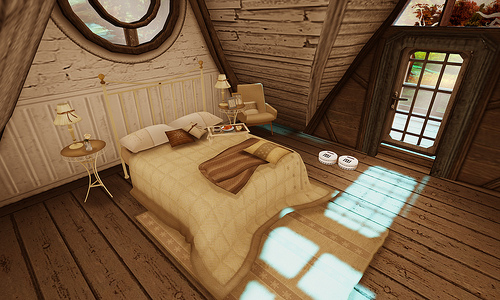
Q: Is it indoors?
A: Yes, it is indoors.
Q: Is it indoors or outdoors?
A: It is indoors.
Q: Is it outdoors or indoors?
A: It is indoors.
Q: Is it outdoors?
A: No, it is indoors.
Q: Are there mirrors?
A: No, there are no mirrors.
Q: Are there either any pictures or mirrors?
A: No, there are no mirrors or pictures.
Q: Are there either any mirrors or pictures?
A: No, there are no mirrors or pictures.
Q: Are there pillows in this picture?
A: Yes, there is a pillow.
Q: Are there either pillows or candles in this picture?
A: Yes, there is a pillow.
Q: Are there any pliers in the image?
A: No, there are no pliers.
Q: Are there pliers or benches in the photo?
A: No, there are no pliers or benches.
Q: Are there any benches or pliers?
A: No, there are no pliers or benches.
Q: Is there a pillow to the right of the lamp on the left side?
A: Yes, there is a pillow to the right of the lamp.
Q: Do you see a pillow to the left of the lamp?
A: No, the pillow is to the right of the lamp.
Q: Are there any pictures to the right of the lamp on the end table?
A: No, there is a pillow to the right of the lamp.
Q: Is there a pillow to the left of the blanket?
A: Yes, there is a pillow to the left of the blanket.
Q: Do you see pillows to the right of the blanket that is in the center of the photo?
A: No, the pillow is to the left of the blanket.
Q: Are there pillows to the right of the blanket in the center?
A: No, the pillow is to the left of the blanket.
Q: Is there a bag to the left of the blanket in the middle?
A: No, there is a pillow to the left of the blanket.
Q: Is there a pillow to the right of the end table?
A: Yes, there is a pillow to the right of the end table.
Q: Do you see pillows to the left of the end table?
A: No, the pillow is to the right of the end table.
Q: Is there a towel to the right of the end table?
A: No, there is a pillow to the right of the end table.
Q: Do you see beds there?
A: Yes, there is a bed.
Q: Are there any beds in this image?
A: Yes, there is a bed.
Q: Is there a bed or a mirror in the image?
A: Yes, there is a bed.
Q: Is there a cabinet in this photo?
A: No, there are no cabinets.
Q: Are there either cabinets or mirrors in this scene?
A: No, there are no cabinets or mirrors.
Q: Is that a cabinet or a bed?
A: That is a bed.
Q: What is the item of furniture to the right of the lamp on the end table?
A: The piece of furniture is a bed.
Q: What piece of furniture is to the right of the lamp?
A: The piece of furniture is a bed.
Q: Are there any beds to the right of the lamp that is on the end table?
A: Yes, there is a bed to the right of the lamp.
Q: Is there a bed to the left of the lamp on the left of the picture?
A: No, the bed is to the right of the lamp.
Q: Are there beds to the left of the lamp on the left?
A: No, the bed is to the right of the lamp.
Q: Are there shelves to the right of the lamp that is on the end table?
A: No, there is a bed to the right of the lamp.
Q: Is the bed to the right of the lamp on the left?
A: Yes, the bed is to the right of the lamp.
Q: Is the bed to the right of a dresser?
A: No, the bed is to the right of the lamp.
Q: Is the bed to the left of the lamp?
A: No, the bed is to the right of the lamp.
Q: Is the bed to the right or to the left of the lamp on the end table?
A: The bed is to the right of the lamp.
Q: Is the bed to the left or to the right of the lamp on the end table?
A: The bed is to the right of the lamp.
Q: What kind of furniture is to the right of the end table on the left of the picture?
A: The piece of furniture is a bed.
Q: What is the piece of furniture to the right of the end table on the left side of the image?
A: The piece of furniture is a bed.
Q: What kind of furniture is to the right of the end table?
A: The piece of furniture is a bed.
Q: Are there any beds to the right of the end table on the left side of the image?
A: Yes, there is a bed to the right of the end table.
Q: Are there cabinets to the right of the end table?
A: No, there is a bed to the right of the end table.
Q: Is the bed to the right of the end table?
A: Yes, the bed is to the right of the end table.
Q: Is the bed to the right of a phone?
A: No, the bed is to the right of the end table.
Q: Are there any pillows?
A: Yes, there is a pillow.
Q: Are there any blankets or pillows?
A: Yes, there is a pillow.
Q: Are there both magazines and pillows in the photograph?
A: No, there is a pillow but no magazines.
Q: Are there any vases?
A: No, there are no vases.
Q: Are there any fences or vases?
A: No, there are no vases or fences.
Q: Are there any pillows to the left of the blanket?
A: Yes, there is a pillow to the left of the blanket.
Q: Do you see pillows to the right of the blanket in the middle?
A: No, the pillow is to the left of the blanket.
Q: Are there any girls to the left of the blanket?
A: No, there is a pillow to the left of the blanket.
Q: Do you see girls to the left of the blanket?
A: No, there is a pillow to the left of the blanket.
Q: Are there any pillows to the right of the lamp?
A: Yes, there is a pillow to the right of the lamp.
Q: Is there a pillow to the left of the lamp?
A: No, the pillow is to the right of the lamp.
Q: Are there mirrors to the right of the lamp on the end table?
A: No, there is a pillow to the right of the lamp.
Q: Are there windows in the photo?
A: Yes, there are windows.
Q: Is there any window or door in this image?
A: Yes, there are windows.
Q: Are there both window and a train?
A: No, there are windows but no trains.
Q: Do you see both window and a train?
A: No, there are windows but no trains.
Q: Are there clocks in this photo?
A: No, there are no clocks.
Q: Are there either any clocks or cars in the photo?
A: No, there are no clocks or cars.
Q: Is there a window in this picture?
A: Yes, there are windows.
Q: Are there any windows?
A: Yes, there are windows.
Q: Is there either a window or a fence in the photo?
A: Yes, there are windows.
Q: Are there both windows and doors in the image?
A: Yes, there are both windows and a door.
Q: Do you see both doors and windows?
A: Yes, there are both windows and a door.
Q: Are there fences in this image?
A: No, there are no fences.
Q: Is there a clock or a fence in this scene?
A: No, there are no fences or clocks.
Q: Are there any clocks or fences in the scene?
A: No, there are no fences or clocks.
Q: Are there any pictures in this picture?
A: No, there are no pictures.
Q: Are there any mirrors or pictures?
A: No, there are no pictures or mirrors.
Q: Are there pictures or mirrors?
A: No, there are no pictures or mirrors.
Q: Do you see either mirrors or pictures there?
A: No, there are no pictures or mirrors.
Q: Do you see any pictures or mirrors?
A: No, there are no pictures or mirrors.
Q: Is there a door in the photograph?
A: Yes, there is a door.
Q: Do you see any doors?
A: Yes, there is a door.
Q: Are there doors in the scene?
A: Yes, there is a door.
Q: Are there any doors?
A: Yes, there is a door.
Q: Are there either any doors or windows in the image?
A: Yes, there is a door.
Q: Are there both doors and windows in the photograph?
A: Yes, there are both a door and a window.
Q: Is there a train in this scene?
A: No, there are no trains.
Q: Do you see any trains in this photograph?
A: No, there are no trains.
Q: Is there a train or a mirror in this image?
A: No, there are no trains or mirrors.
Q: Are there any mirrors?
A: No, there are no mirrors.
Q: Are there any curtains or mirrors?
A: No, there are no mirrors or curtains.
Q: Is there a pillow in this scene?
A: Yes, there is a pillow.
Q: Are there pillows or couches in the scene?
A: Yes, there is a pillow.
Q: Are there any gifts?
A: No, there are no gifts.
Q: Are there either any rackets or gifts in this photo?
A: No, there are no gifts or rackets.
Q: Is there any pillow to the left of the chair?
A: Yes, there is a pillow to the left of the chair.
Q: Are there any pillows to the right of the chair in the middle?
A: No, the pillow is to the left of the chair.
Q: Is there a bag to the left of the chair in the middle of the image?
A: No, there is a pillow to the left of the chair.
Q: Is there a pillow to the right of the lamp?
A: Yes, there is a pillow to the right of the lamp.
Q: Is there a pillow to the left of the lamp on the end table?
A: No, the pillow is to the right of the lamp.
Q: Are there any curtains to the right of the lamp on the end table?
A: No, there is a pillow to the right of the lamp.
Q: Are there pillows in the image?
A: Yes, there are pillows.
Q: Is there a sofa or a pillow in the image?
A: Yes, there are pillows.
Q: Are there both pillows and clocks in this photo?
A: No, there are pillows but no clocks.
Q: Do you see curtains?
A: No, there are no curtains.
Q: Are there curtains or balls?
A: No, there are no curtains or balls.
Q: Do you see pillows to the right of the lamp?
A: Yes, there are pillows to the right of the lamp.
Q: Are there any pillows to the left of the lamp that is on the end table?
A: No, the pillows are to the right of the lamp.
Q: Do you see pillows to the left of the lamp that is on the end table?
A: No, the pillows are to the right of the lamp.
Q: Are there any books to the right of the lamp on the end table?
A: No, there are pillows to the right of the lamp.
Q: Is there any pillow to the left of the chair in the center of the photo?
A: Yes, there are pillows to the left of the chair.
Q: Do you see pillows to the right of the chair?
A: No, the pillows are to the left of the chair.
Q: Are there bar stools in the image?
A: No, there are no bar stools.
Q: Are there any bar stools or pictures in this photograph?
A: No, there are no bar stools or pictures.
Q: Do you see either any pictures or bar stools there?
A: No, there are no bar stools or pictures.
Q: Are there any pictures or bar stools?
A: No, there are no bar stools or pictures.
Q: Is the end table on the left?
A: Yes, the end table is on the left of the image.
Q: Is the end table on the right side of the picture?
A: No, the end table is on the left of the image.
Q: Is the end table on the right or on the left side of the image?
A: The end table is on the left of the image.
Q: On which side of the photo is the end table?
A: The end table is on the left of the image.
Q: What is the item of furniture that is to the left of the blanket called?
A: The piece of furniture is an end table.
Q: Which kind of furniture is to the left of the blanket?
A: The piece of furniture is an end table.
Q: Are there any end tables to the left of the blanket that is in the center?
A: Yes, there is an end table to the left of the blanket.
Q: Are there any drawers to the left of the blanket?
A: No, there is an end table to the left of the blanket.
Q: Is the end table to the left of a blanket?
A: Yes, the end table is to the left of a blanket.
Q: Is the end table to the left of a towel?
A: No, the end table is to the left of a blanket.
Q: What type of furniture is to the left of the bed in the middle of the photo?
A: The piece of furniture is an end table.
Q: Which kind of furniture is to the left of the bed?
A: The piece of furniture is an end table.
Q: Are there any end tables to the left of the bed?
A: Yes, there is an end table to the left of the bed.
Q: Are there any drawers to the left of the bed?
A: No, there is an end table to the left of the bed.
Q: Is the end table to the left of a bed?
A: Yes, the end table is to the left of a bed.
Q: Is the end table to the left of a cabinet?
A: No, the end table is to the left of a bed.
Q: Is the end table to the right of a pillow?
A: No, the end table is to the left of a pillow.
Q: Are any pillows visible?
A: Yes, there is a pillow.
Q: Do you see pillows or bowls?
A: Yes, there is a pillow.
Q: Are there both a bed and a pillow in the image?
A: Yes, there are both a pillow and a bed.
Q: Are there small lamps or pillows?
A: Yes, there is a small pillow.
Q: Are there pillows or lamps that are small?
A: Yes, the pillow is small.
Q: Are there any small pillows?
A: Yes, there is a small pillow.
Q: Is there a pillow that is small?
A: Yes, there is a small pillow.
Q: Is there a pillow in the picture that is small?
A: Yes, there is a pillow that is small.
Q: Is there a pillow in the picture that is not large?
A: Yes, there is a small pillow.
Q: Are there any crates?
A: No, there are no crates.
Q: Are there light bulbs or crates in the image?
A: No, there are no crates or light bulbs.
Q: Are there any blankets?
A: Yes, there is a blanket.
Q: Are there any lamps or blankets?
A: Yes, there is a blanket.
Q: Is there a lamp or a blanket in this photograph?
A: Yes, there is a blanket.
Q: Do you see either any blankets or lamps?
A: Yes, there is a blanket.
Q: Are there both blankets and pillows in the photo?
A: Yes, there are both a blanket and a pillow.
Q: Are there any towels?
A: No, there are no towels.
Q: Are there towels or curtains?
A: No, there are no towels or curtains.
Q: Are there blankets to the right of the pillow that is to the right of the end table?
A: Yes, there is a blanket to the right of the pillow.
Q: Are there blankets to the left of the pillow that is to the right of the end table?
A: No, the blanket is to the right of the pillow.